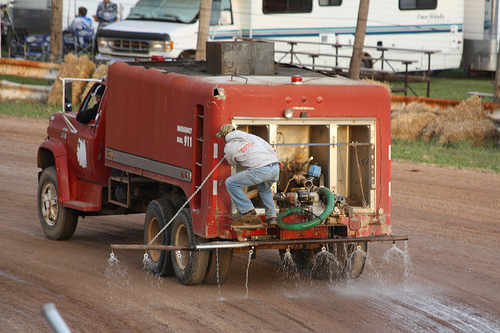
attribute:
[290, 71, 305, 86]
light — red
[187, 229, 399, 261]
watering system — long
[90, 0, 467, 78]
white truck — parked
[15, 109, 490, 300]
road — dirt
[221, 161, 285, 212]
jeans — blue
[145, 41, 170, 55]
headlight — clear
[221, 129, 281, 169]
shirt — blue, white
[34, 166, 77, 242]
tire — thick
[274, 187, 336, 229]
pipe — green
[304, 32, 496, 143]
rail — rusty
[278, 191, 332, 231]
hose — green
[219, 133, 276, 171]
hoodie — grey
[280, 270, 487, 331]
road — dirt